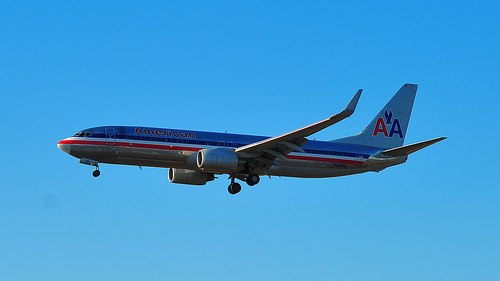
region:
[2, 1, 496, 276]
a clear blue sky above the plane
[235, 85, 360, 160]
the plane's left wing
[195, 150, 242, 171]
the plane's left jet engine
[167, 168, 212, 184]
the plane's right jet engine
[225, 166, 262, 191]
the under-wing landing gear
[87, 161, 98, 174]
the nose landing gear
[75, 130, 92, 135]
cockpit windows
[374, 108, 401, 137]
American Airlines logo on the tail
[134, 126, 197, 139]
the Airline's name on the fuselage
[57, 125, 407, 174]
the airplane's fuselage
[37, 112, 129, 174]
front of a plane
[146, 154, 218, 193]
turbine of a plane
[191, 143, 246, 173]
turbine of a plane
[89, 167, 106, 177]
wheel of a plane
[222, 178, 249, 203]
wheel of a plane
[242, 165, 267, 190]
wheel of a plane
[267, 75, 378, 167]
wing of a plane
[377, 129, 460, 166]
wing of a plane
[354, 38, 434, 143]
wing of a plane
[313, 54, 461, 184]
tail of a plane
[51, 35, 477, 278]
Plane is flying in the sky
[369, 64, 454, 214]
Tail on the back of plane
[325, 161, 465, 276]
The sky is blue and cloud free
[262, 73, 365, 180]
Wing on the plain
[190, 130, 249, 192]
Jet engine on side of plane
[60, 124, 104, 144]
Window on front of plane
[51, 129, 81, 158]
Nose on the plane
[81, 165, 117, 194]
Small wheel on the front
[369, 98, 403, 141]
Logo on the tail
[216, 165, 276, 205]
Several wheels on the plane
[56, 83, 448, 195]
American Airlines plane flying in sky.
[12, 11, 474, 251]
airplane flying through the sky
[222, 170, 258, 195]
landing gear in motion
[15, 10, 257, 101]
clear blue cloudless sky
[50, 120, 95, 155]
nose and cockpit of the plane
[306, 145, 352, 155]
row of windows in the coach section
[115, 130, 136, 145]
blue white and red stripes on the fuselage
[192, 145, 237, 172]
one of the aircraft's two engines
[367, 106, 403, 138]
corporate logo of the carrier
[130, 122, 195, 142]
written out name of the carrier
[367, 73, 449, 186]
tail section of the plane